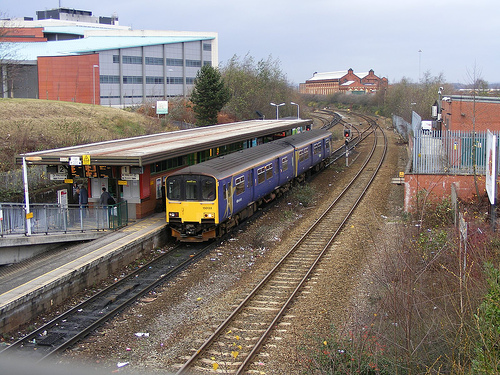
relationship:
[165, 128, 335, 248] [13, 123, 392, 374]
train on tracks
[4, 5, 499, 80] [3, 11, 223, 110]
sky above building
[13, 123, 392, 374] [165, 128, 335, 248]
tracks near train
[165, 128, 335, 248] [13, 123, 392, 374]
train near tracks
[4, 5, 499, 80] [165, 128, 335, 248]
sky above train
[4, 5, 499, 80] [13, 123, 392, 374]
sky above tracks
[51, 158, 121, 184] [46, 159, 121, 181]
billboard showing information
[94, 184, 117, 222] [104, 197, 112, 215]
person carrying backpack